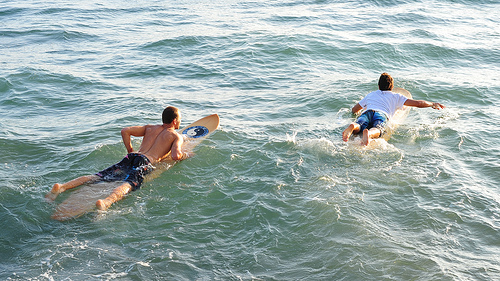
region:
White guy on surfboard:
[45, 104, 187, 215]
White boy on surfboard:
[342, 68, 442, 145]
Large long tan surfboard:
[51, 112, 221, 222]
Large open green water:
[0, 1, 499, 278]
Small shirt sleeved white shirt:
[357, 89, 409, 119]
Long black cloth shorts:
[97, 151, 157, 191]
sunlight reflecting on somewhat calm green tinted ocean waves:
[223, 177, 498, 279]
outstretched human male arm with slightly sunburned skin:
[408, 91, 445, 112]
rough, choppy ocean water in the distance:
[0, 2, 498, 57]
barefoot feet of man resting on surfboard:
[338, 120, 373, 149]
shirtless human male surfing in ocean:
[25, 100, 224, 219]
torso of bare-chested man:
[114, 95, 188, 162]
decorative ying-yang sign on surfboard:
[183, 122, 207, 139]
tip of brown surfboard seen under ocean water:
[48, 193, 93, 220]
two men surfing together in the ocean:
[42, 67, 444, 223]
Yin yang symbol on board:
[182, 123, 210, 138]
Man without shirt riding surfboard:
[44, 104, 220, 224]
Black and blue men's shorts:
[87, 149, 155, 191]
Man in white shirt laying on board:
[340, 71, 445, 146]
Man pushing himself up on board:
[47, 103, 220, 225]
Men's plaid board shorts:
[352, 108, 389, 137]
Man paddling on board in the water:
[340, 69, 445, 150]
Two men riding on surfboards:
[3, 72, 445, 222]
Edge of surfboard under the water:
[50, 183, 120, 221]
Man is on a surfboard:
[18, 78, 240, 233]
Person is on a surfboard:
[327, 50, 457, 158]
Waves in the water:
[256, 195, 416, 263]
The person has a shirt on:
[348, 83, 410, 118]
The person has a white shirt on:
[347, 76, 413, 118]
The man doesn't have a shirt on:
[107, 97, 200, 164]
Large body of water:
[235, 180, 413, 270]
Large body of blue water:
[236, 187, 393, 268]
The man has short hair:
[158, 103, 183, 134]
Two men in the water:
[26, 32, 468, 237]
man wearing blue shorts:
[95, 145, 152, 197]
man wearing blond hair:
[156, 103, 184, 135]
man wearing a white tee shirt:
[348, 80, 410, 122]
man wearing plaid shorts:
[343, 97, 385, 128]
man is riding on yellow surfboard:
[41, 105, 218, 224]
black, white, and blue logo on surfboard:
[51, 113, 219, 220]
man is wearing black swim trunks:
[44, 106, 194, 219]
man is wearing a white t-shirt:
[342, 70, 444, 147]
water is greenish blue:
[1, 1, 498, 280]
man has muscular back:
[45, 105, 196, 216]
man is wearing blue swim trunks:
[341, 72, 446, 149]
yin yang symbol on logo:
[181, 126, 208, 138]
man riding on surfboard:
[343, 72, 443, 149]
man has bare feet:
[46, 106, 195, 221]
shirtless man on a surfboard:
[43, 72, 223, 227]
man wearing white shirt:
[337, 73, 435, 155]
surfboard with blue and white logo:
[45, 97, 227, 247]